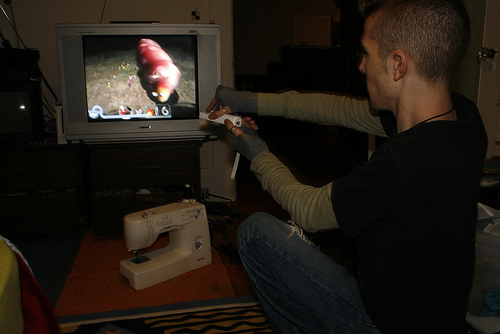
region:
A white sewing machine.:
[90, 188, 232, 293]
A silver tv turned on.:
[37, 4, 241, 154]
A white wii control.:
[185, 86, 260, 158]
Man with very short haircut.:
[338, 2, 483, 137]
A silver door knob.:
[467, 42, 499, 69]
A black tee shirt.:
[314, 95, 498, 329]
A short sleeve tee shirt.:
[328, 122, 499, 322]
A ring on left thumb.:
[220, 113, 262, 150]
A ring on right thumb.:
[205, 96, 250, 123]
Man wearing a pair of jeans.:
[232, 0, 492, 328]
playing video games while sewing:
[38, 9, 478, 328]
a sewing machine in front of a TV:
[91, 186, 231, 286]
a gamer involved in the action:
[61, 6, 463, 201]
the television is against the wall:
[31, 7, 256, 142]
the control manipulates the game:
[151, 70, 286, 155]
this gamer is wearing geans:
[221, 202, 398, 327]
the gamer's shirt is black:
[267, 96, 482, 327]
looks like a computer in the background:
[2, 5, 57, 310]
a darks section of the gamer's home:
[226, 5, 486, 181]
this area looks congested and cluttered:
[18, 11, 489, 327]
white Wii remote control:
[195, 90, 260, 141]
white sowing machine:
[110, 191, 235, 286]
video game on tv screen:
[47, 10, 253, 170]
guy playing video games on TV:
[231, 25, 492, 320]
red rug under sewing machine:
[67, 226, 217, 328]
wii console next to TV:
[46, 103, 77, 146]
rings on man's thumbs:
[218, 92, 269, 155]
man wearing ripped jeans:
[248, 182, 363, 290]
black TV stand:
[82, 136, 227, 231]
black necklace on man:
[401, 98, 480, 135]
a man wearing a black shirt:
[184, 11, 499, 330]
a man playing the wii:
[154, 0, 499, 298]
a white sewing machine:
[71, 156, 257, 331]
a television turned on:
[47, 9, 258, 178]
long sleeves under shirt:
[201, 42, 486, 270]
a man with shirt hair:
[153, 4, 499, 314]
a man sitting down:
[196, 3, 464, 330]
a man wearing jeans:
[199, 4, 489, 331]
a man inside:
[158, 10, 497, 324]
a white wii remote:
[167, 50, 304, 196]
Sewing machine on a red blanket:
[112, 195, 219, 287]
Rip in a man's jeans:
[286, 217, 323, 249]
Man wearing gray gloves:
[215, 87, 272, 159]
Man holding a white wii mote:
[198, 111, 261, 135]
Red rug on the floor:
[63, 234, 255, 308]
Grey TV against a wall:
[56, 22, 226, 140]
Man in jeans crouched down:
[237, 207, 379, 329]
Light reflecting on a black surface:
[15, 97, 30, 114]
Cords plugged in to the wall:
[200, 185, 240, 220]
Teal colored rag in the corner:
[483, 291, 498, 320]